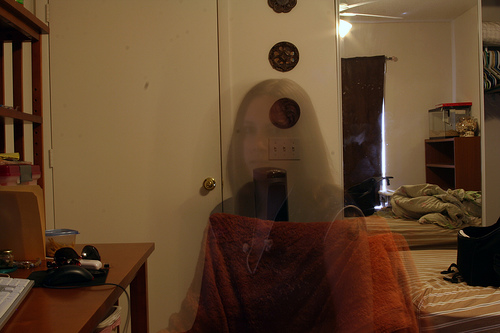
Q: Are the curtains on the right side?
A: Yes, the curtains are on the right of the image.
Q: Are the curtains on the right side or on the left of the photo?
A: The curtains are on the right of the image.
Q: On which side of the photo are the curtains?
A: The curtains are on the right of the image.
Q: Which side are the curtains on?
A: The curtains are on the right of the image.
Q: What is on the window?
A: The curtains are on the window.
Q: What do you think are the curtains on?
A: The curtains are on the window.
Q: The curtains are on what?
A: The curtains are on the window.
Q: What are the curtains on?
A: The curtains are on the window.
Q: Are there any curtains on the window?
A: Yes, there are curtains on the window.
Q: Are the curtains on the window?
A: Yes, the curtains are on the window.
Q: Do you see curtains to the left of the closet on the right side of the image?
A: Yes, there are curtains to the left of the closet.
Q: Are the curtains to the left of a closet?
A: Yes, the curtains are to the left of a closet.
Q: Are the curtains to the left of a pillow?
A: No, the curtains are to the left of a closet.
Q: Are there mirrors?
A: Yes, there is a mirror.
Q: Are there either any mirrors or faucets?
A: Yes, there is a mirror.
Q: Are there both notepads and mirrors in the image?
A: No, there is a mirror but no notepads.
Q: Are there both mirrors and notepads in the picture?
A: No, there is a mirror but no notepads.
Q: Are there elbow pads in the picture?
A: No, there are no elbow pads.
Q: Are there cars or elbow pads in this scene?
A: No, there are no elbow pads or cars.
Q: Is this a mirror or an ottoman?
A: This is a mirror.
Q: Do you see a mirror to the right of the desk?
A: Yes, there is a mirror to the right of the desk.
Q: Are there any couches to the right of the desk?
A: No, there is a mirror to the right of the desk.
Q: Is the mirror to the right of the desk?
A: Yes, the mirror is to the right of the desk.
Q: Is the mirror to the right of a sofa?
A: No, the mirror is to the right of the desk.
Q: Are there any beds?
A: Yes, there is a bed.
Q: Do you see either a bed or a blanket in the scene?
A: Yes, there is a bed.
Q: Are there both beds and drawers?
A: No, there is a bed but no drawers.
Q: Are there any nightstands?
A: No, there are no nightstands.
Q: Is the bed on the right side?
A: Yes, the bed is on the right of the image.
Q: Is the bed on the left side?
A: No, the bed is on the right of the image.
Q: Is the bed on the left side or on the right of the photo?
A: The bed is on the right of the image.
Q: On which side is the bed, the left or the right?
A: The bed is on the right of the image.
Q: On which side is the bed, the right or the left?
A: The bed is on the right of the image.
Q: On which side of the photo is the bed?
A: The bed is on the right of the image.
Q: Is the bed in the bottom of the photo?
A: Yes, the bed is in the bottom of the image.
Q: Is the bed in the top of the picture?
A: No, the bed is in the bottom of the image.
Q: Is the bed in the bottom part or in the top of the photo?
A: The bed is in the bottom of the image.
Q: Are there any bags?
A: Yes, there is a bag.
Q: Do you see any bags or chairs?
A: Yes, there is a bag.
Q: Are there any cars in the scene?
A: No, there are no cars.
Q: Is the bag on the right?
A: Yes, the bag is on the right of the image.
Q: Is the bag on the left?
A: No, the bag is on the right of the image.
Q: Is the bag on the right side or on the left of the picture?
A: The bag is on the right of the image.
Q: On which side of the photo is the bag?
A: The bag is on the right of the image.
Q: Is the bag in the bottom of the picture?
A: Yes, the bag is in the bottom of the image.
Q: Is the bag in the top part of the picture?
A: No, the bag is in the bottom of the image.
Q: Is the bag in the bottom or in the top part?
A: The bag is in the bottom of the image.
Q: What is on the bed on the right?
A: The bag is on the bed.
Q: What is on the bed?
A: The bag is on the bed.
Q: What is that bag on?
A: The bag is on the bed.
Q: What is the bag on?
A: The bag is on the bed.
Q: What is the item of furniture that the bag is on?
A: The piece of furniture is a bed.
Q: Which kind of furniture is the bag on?
A: The bag is on the bed.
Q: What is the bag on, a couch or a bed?
A: The bag is on a bed.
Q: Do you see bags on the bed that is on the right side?
A: Yes, there is a bag on the bed.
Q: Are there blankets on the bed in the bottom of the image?
A: No, there is a bag on the bed.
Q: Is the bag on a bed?
A: Yes, the bag is on a bed.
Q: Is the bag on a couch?
A: No, the bag is on a bed.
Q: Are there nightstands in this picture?
A: No, there are no nightstands.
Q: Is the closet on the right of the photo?
A: Yes, the closet is on the right of the image.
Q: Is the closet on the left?
A: No, the closet is on the right of the image.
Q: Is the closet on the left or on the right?
A: The closet is on the right of the image.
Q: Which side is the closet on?
A: The closet is on the right of the image.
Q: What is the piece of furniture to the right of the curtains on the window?
A: The piece of furniture is a closet.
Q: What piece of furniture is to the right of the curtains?
A: The piece of furniture is a closet.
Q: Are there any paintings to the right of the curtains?
A: No, there is a closet to the right of the curtains.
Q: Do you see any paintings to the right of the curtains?
A: No, there is a closet to the right of the curtains.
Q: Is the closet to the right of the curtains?
A: Yes, the closet is to the right of the curtains.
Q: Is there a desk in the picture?
A: Yes, there is a desk.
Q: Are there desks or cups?
A: Yes, there is a desk.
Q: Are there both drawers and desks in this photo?
A: No, there is a desk but no drawers.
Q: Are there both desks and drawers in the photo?
A: No, there is a desk but no drawers.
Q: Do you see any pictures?
A: No, there are no pictures.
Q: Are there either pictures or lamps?
A: No, there are no pictures or lamps.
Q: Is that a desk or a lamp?
A: That is a desk.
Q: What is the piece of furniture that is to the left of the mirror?
A: The piece of furniture is a desk.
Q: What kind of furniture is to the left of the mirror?
A: The piece of furniture is a desk.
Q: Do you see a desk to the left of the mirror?
A: Yes, there is a desk to the left of the mirror.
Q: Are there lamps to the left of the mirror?
A: No, there is a desk to the left of the mirror.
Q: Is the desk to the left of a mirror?
A: Yes, the desk is to the left of a mirror.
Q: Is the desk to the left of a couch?
A: No, the desk is to the left of a mirror.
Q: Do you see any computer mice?
A: Yes, there is a computer mouse.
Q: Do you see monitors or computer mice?
A: Yes, there is a computer mouse.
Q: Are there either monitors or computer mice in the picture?
A: Yes, there is a computer mouse.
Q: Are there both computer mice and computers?
A: No, there is a computer mouse but no computers.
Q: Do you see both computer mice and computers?
A: No, there is a computer mouse but no computers.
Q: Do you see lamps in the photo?
A: No, there are no lamps.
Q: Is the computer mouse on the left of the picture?
A: Yes, the computer mouse is on the left of the image.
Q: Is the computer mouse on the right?
A: No, the computer mouse is on the left of the image.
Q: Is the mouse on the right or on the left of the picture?
A: The mouse is on the left of the image.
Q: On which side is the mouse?
A: The mouse is on the left of the image.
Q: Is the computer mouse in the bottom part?
A: Yes, the computer mouse is in the bottom of the image.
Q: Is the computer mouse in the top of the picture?
A: No, the computer mouse is in the bottom of the image.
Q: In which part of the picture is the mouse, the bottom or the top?
A: The mouse is in the bottom of the image.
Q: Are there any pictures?
A: No, there are no pictures.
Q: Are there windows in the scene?
A: Yes, there is a window.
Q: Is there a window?
A: Yes, there is a window.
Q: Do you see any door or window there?
A: Yes, there is a window.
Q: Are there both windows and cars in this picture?
A: No, there is a window but no cars.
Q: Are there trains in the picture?
A: No, there are no trains.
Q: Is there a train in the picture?
A: No, there are no trains.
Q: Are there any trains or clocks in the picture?
A: No, there are no trains or clocks.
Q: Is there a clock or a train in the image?
A: No, there are no trains or clocks.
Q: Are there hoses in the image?
A: No, there are no hoses.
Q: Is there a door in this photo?
A: Yes, there is a door.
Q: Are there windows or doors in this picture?
A: Yes, there is a door.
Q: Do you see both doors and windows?
A: Yes, there are both a door and a window.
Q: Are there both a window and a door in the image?
A: Yes, there are both a door and a window.